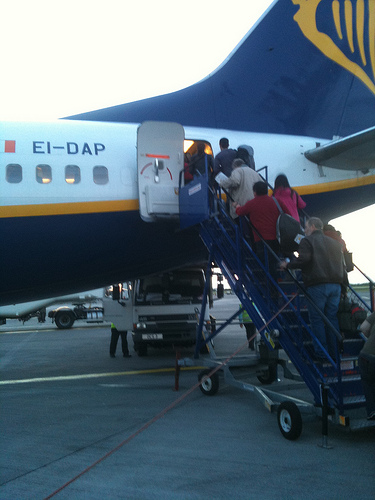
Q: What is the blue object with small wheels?
A: Movable stairs.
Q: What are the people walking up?
A: Steps.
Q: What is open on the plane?
A: Door.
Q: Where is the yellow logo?
A: Plane tail.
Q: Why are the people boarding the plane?
A: To travel.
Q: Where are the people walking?
A: Up the stairs.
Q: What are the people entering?
A: Plane.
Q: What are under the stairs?
A: Wheels.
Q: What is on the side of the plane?
A: Windows.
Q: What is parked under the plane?
A: Van.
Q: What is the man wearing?
A: Jean jacket.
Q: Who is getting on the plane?
A: Passengers.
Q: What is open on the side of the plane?
A: Rear exit door.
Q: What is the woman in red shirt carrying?
A: Bag.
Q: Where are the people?
A: On a staircase.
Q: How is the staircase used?
A: To help people board a plane.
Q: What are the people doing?
A: Getting on a plane.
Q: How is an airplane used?
A: To transport people.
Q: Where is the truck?
A: Behind the plane.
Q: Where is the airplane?
A: At an airport.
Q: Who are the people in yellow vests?
A: Airport workers.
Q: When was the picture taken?
A: During day hours.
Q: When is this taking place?
A: Daytime.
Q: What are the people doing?
A: Boarding a plane.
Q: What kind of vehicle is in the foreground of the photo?
A: Airplane.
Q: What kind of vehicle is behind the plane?
A: Van.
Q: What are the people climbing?
A: Stairs.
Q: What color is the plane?
A: White, blue and yellow.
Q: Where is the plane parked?
A: Concrete tarmac.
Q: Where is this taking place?
A: At the airport.